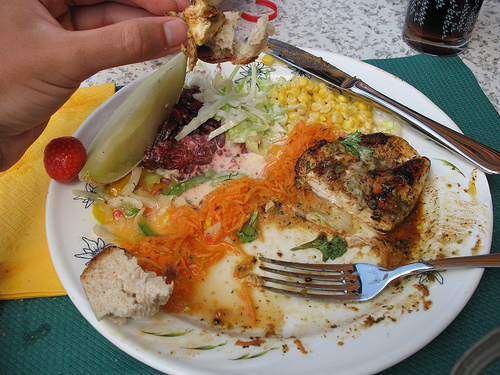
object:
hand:
[0, 0, 204, 175]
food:
[41, 0, 432, 323]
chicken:
[295, 133, 432, 232]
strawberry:
[43, 136, 83, 184]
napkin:
[0, 205, 40, 291]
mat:
[433, 66, 469, 102]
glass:
[402, 0, 481, 57]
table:
[328, 15, 385, 50]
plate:
[50, 209, 89, 264]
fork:
[258, 253, 500, 303]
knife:
[262, 37, 500, 176]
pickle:
[155, 136, 203, 167]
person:
[0, 0, 199, 171]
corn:
[285, 84, 325, 119]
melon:
[76, 52, 186, 186]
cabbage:
[181, 64, 275, 143]